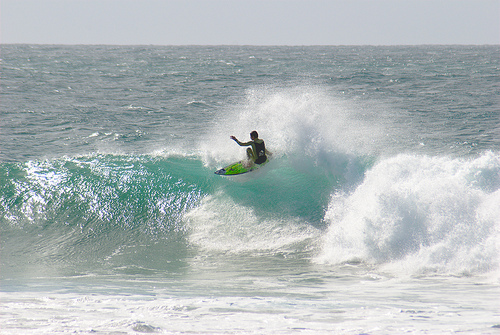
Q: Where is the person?
A: In the water.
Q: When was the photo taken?
A: Daytime.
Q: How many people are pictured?
A: One.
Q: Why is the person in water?
A: They are surfing.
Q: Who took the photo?
A: A tourist.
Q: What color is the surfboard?
A: Yellow and green.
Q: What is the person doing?
A: Riding a wave.